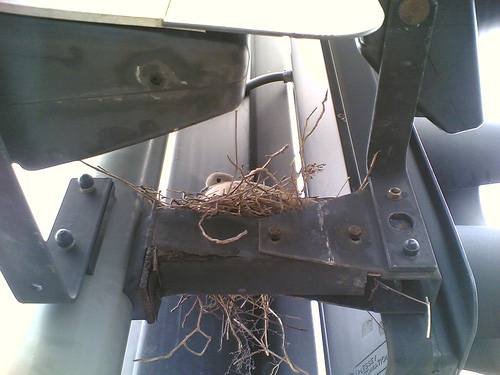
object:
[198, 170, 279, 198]
bird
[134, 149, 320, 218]
nest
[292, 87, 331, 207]
twig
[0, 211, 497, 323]
structure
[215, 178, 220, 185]
eye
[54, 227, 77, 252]
bolts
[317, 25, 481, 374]
bridge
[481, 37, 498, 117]
sky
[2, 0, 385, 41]
projection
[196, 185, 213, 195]
beak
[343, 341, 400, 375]
writing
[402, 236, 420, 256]
bolt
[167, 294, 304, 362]
nest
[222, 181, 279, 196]
feathers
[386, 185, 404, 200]
bolt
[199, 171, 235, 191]
head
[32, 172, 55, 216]
sunlight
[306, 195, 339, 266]
poop